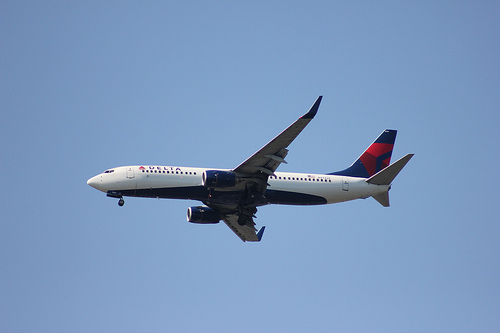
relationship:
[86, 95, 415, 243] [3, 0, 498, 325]
airplane in sky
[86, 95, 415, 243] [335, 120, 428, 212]
airplane has tail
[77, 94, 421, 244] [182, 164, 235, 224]
airplane has engines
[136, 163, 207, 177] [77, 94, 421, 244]
windows are on airplane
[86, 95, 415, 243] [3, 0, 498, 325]
airplane flying in sky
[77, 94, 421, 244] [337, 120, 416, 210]
airplane has tail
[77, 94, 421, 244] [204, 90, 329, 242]
airplane has wings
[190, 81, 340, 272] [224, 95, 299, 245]
airplane wings have underside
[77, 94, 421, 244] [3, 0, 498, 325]
airplane flying in sky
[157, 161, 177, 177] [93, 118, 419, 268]
letter on side of plane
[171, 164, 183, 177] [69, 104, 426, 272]
letter on side of plane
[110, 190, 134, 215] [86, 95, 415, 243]
front wheel of airplane